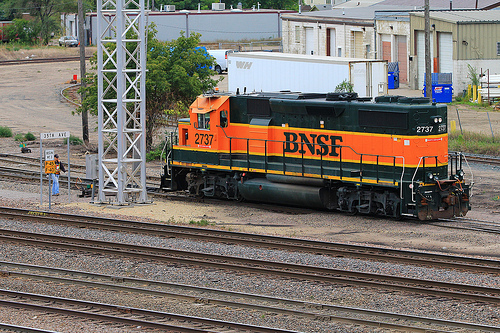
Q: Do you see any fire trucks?
A: No, there are no fire trucks.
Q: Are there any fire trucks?
A: No, there are no fire trucks.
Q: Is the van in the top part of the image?
A: Yes, the van is in the top of the image.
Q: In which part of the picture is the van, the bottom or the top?
A: The van is in the top of the image.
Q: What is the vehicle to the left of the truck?
A: The vehicle is a van.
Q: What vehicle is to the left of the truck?
A: The vehicle is a van.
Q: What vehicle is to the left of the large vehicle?
A: The vehicle is a van.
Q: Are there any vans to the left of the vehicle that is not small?
A: Yes, there is a van to the left of the truck.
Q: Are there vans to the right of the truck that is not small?
A: No, the van is to the left of the truck.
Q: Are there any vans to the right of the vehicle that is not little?
A: No, the van is to the left of the truck.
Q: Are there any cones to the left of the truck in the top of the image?
A: No, there is a van to the left of the truck.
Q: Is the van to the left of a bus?
A: No, the van is to the left of the truck.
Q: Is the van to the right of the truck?
A: No, the van is to the left of the truck.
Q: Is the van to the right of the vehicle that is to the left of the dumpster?
A: No, the van is to the left of the truck.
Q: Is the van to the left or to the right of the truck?
A: The van is to the left of the truck.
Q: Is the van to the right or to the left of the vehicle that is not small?
A: The van is to the left of the truck.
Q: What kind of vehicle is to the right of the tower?
A: The vehicle is a van.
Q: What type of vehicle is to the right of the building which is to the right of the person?
A: The vehicle is a van.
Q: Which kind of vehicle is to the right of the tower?
A: The vehicle is a van.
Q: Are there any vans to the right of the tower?
A: Yes, there is a van to the right of the tower.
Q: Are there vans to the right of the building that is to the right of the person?
A: Yes, there is a van to the right of the tower.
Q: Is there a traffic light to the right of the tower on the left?
A: No, there is a van to the right of the tower.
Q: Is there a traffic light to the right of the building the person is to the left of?
A: No, there is a van to the right of the tower.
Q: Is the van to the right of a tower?
A: Yes, the van is to the right of a tower.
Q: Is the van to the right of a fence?
A: No, the van is to the right of a tower.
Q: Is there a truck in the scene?
A: Yes, there is a truck.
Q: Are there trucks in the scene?
A: Yes, there is a truck.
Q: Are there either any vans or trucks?
A: Yes, there is a truck.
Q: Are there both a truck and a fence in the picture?
A: No, there is a truck but no fences.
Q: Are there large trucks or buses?
A: Yes, there is a large truck.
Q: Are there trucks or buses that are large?
A: Yes, the truck is large.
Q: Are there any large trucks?
A: Yes, there is a large truck.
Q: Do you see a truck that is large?
A: Yes, there is a truck that is large.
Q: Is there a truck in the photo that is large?
A: Yes, there is a truck that is large.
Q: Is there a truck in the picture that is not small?
A: Yes, there is a large truck.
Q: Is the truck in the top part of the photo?
A: Yes, the truck is in the top of the image.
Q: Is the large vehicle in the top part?
A: Yes, the truck is in the top of the image.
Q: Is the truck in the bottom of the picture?
A: No, the truck is in the top of the image.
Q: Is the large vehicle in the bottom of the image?
A: No, the truck is in the top of the image.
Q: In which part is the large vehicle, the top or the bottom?
A: The truck is in the top of the image.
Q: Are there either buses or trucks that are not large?
A: No, there is a truck but it is large.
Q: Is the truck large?
A: Yes, the truck is large.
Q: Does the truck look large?
A: Yes, the truck is large.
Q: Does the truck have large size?
A: Yes, the truck is large.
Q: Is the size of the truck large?
A: Yes, the truck is large.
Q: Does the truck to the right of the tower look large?
A: Yes, the truck is large.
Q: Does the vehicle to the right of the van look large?
A: Yes, the truck is large.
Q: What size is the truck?
A: The truck is large.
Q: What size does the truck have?
A: The truck has large size.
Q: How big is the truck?
A: The truck is large.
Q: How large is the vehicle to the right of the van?
A: The truck is large.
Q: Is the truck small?
A: No, the truck is large.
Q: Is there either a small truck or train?
A: No, there is a truck but it is large.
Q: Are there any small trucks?
A: No, there is a truck but it is large.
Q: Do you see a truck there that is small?
A: No, there is a truck but it is large.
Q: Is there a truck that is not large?
A: No, there is a truck but it is large.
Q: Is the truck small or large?
A: The truck is large.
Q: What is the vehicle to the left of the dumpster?
A: The vehicle is a truck.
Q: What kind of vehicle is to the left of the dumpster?
A: The vehicle is a truck.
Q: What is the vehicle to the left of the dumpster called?
A: The vehicle is a truck.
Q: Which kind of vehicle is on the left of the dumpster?
A: The vehicle is a truck.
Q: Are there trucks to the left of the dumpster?
A: Yes, there is a truck to the left of the dumpster.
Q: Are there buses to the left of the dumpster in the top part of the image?
A: No, there is a truck to the left of the dumpster.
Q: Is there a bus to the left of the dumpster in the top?
A: No, there is a truck to the left of the dumpster.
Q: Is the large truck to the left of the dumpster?
A: Yes, the truck is to the left of the dumpster.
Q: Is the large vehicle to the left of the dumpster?
A: Yes, the truck is to the left of the dumpster.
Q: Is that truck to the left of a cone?
A: No, the truck is to the left of the dumpster.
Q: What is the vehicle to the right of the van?
A: The vehicle is a truck.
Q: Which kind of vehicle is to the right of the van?
A: The vehicle is a truck.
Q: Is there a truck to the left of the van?
A: No, the truck is to the right of the van.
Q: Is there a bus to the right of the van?
A: No, there is a truck to the right of the van.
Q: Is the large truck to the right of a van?
A: Yes, the truck is to the right of a van.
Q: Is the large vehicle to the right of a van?
A: Yes, the truck is to the right of a van.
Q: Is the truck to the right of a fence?
A: No, the truck is to the right of a van.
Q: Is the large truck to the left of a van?
A: No, the truck is to the right of a van.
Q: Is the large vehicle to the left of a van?
A: No, the truck is to the right of a van.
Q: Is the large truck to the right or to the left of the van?
A: The truck is to the right of the van.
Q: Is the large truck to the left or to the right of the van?
A: The truck is to the right of the van.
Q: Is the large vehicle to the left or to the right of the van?
A: The truck is to the right of the van.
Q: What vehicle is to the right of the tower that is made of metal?
A: The vehicle is a truck.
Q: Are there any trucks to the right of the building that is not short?
A: Yes, there is a truck to the right of the tower.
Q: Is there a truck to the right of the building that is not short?
A: Yes, there is a truck to the right of the tower.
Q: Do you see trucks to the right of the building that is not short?
A: Yes, there is a truck to the right of the tower.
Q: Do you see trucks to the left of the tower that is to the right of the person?
A: No, the truck is to the right of the tower.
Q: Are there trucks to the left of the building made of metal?
A: No, the truck is to the right of the tower.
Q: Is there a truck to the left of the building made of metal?
A: No, the truck is to the right of the tower.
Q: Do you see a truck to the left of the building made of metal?
A: No, the truck is to the right of the tower.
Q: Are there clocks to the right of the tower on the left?
A: No, there is a truck to the right of the tower.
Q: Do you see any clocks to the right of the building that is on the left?
A: No, there is a truck to the right of the tower.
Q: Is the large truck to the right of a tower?
A: Yes, the truck is to the right of a tower.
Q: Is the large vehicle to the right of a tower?
A: Yes, the truck is to the right of a tower.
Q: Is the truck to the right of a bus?
A: No, the truck is to the right of a tower.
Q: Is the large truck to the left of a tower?
A: No, the truck is to the right of a tower.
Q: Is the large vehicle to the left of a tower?
A: No, the truck is to the right of a tower.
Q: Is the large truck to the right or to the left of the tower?
A: The truck is to the right of the tower.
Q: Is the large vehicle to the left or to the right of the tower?
A: The truck is to the right of the tower.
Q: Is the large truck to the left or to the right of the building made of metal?
A: The truck is to the right of the tower.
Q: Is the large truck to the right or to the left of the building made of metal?
A: The truck is to the right of the tower.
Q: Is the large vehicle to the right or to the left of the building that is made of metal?
A: The truck is to the right of the tower.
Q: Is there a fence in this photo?
A: No, there are no fences.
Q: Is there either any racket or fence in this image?
A: No, there are no fences or rackets.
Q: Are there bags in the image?
A: No, there are no bags.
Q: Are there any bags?
A: No, there are no bags.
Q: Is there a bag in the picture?
A: No, there are no bags.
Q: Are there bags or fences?
A: No, there are no bags or fences.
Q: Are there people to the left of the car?
A: Yes, there is a person to the left of the car.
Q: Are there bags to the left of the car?
A: No, there is a person to the left of the car.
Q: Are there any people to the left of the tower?
A: Yes, there is a person to the left of the tower.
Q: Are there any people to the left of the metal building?
A: Yes, there is a person to the left of the tower.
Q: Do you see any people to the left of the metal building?
A: Yes, there is a person to the left of the tower.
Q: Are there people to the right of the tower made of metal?
A: No, the person is to the left of the tower.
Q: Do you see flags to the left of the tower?
A: No, there is a person to the left of the tower.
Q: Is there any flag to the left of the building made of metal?
A: No, there is a person to the left of the tower.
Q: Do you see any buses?
A: No, there are no buses.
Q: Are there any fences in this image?
A: No, there are no fences.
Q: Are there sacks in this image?
A: No, there are no sacks.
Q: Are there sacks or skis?
A: No, there are no sacks or skis.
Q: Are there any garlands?
A: No, there are no garlands.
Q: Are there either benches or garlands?
A: No, there are no garlands or benches.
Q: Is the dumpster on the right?
A: Yes, the dumpster is on the right of the image.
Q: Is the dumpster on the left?
A: No, the dumpster is on the right of the image.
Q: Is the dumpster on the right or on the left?
A: The dumpster is on the right of the image.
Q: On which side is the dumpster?
A: The dumpster is on the right of the image.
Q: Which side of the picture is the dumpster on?
A: The dumpster is on the right of the image.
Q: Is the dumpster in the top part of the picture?
A: Yes, the dumpster is in the top of the image.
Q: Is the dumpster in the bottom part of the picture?
A: No, the dumpster is in the top of the image.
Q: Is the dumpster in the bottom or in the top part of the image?
A: The dumpster is in the top of the image.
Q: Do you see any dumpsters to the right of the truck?
A: Yes, there is a dumpster to the right of the truck.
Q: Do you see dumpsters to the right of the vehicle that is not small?
A: Yes, there is a dumpster to the right of the truck.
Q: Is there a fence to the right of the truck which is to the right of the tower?
A: No, there is a dumpster to the right of the truck.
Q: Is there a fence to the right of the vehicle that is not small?
A: No, there is a dumpster to the right of the truck.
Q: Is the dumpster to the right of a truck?
A: Yes, the dumpster is to the right of a truck.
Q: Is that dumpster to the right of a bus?
A: No, the dumpster is to the right of a truck.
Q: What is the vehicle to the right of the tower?
A: The vehicle is a car.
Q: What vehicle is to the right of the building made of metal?
A: The vehicle is a car.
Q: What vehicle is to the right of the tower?
A: The vehicle is a car.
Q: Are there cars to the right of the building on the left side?
A: Yes, there is a car to the right of the tower.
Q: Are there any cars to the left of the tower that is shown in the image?
A: No, the car is to the right of the tower.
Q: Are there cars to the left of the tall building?
A: No, the car is to the right of the tower.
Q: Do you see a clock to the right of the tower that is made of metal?
A: No, there is a car to the right of the tower.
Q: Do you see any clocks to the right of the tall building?
A: No, there is a car to the right of the tower.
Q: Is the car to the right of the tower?
A: Yes, the car is to the right of the tower.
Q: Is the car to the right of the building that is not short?
A: Yes, the car is to the right of the tower.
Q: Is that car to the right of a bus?
A: No, the car is to the right of the tower.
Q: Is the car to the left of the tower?
A: No, the car is to the right of the tower.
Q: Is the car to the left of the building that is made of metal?
A: No, the car is to the right of the tower.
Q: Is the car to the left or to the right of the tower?
A: The car is to the right of the tower.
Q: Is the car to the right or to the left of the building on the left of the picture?
A: The car is to the right of the tower.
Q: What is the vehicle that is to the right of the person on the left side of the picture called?
A: The vehicle is a car.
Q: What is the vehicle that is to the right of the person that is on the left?
A: The vehicle is a car.